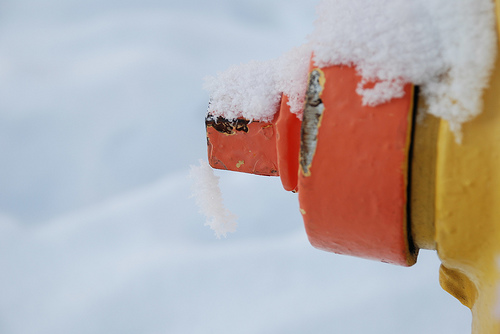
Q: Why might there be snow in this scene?
A: It's winter.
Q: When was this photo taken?
A: Daytime.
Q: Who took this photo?
A: Photographer.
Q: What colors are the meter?
A: Orange and yellow.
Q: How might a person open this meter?
A: With wrench.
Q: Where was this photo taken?
A: Near hydrant.